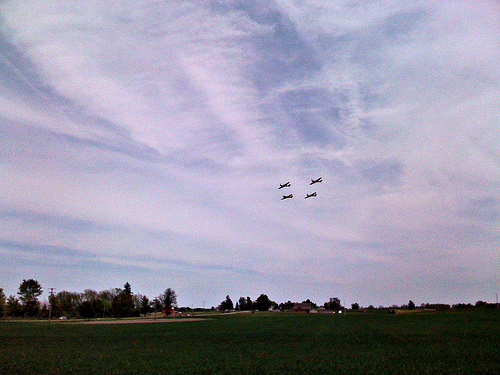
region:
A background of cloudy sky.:
[1, 0, 499, 305]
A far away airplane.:
[308, 175, 324, 187]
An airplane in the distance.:
[277, 178, 293, 192]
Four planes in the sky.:
[276, 173, 325, 205]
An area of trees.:
[0, 277, 179, 320]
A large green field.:
[0, 308, 499, 373]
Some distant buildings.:
[289, 303, 334, 313]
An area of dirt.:
[79, 315, 211, 325]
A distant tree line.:
[215, 292, 499, 315]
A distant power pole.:
[46, 285, 60, 322]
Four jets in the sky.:
[268, 163, 330, 206]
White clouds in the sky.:
[0, 0, 498, 307]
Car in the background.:
[55, 313, 70, 321]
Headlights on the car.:
[56, 313, 68, 323]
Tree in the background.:
[154, 285, 181, 317]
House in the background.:
[287, 300, 329, 312]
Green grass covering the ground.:
[1, 310, 498, 374]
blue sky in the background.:
[0, 0, 495, 307]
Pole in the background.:
[200, 299, 208, 311]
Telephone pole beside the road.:
[41, 281, 56, 327]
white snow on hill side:
[369, 281, 399, 320]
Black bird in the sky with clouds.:
[27, 35, 49, 37]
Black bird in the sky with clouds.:
[305, 265, 342, 285]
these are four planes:
[224, 105, 351, 245]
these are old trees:
[31, 267, 270, 363]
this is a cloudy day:
[107, 29, 279, 241]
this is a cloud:
[137, 176, 286, 239]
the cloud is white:
[126, 190, 218, 232]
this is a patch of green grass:
[179, 342, 184, 346]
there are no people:
[250, 312, 267, 333]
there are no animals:
[172, 284, 219, 343]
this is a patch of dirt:
[104, 324, 183, 340]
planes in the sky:
[231, 136, 397, 236]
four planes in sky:
[254, 155, 356, 221]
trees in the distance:
[0, 259, 299, 344]